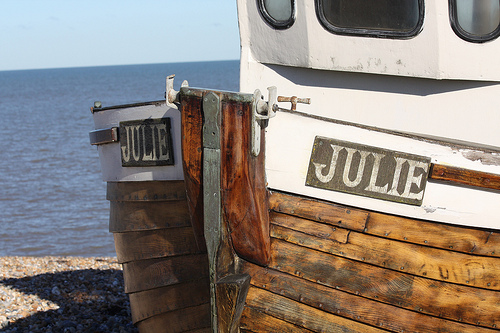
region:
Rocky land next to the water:
[1, 253, 130, 331]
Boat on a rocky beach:
[89, 2, 499, 330]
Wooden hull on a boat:
[104, 175, 499, 331]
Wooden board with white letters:
[301, 134, 433, 209]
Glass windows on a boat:
[247, 0, 499, 43]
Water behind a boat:
[2, 59, 241, 254]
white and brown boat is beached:
[86, 4, 496, 331]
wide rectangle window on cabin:
[310, 0, 427, 42]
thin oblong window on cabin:
[445, 0, 499, 45]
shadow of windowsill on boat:
[257, 54, 498, 98]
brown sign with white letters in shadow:
[115, 111, 177, 172]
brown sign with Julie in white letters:
[302, 127, 434, 208]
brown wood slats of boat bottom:
[227, 180, 497, 331]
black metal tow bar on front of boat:
[165, 65, 277, 330]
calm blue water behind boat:
[0, 60, 240, 252]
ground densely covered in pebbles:
[3, 254, 138, 331]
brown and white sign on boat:
[298, 135, 445, 212]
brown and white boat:
[87, 2, 498, 332]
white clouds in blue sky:
[7, 3, 62, 43]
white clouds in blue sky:
[64, 21, 121, 53]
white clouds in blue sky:
[140, 15, 200, 46]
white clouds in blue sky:
[30, 16, 104, 60]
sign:
[107, 98, 182, 175]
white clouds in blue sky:
[82, 13, 169, 44]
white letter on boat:
[311, 140, 345, 185]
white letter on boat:
[341, 146, 367, 186]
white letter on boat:
[365, 150, 389, 196]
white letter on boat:
[387, 153, 404, 199]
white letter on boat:
[402, 155, 426, 200]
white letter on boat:
[153, 123, 170, 163]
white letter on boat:
[148, 123, 158, 162]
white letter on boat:
[140, 123, 155, 163]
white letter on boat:
[128, 124, 143, 161]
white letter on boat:
[119, 124, 133, 164]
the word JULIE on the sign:
[304, 135, 430, 209]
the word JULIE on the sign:
[119, 117, 174, 167]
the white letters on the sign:
[303, 134, 429, 207]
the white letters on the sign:
[116, 115, 176, 167]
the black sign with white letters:
[303, 133, 430, 208]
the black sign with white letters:
[118, 117, 174, 167]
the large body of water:
[0, 59, 239, 256]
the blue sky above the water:
[1, 0, 242, 70]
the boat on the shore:
[1, 0, 499, 330]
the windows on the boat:
[88, 0, 499, 332]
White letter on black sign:
[111, 120, 131, 169]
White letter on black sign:
[125, 120, 142, 167]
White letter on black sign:
[140, 123, 150, 166]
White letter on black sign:
[146, 118, 161, 169]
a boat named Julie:
[289, 121, 444, 224]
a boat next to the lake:
[76, 42, 483, 293]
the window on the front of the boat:
[311, 3, 441, 43]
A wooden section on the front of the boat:
[254, 190, 493, 317]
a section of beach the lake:
[14, 231, 107, 293]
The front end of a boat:
[214, 7, 489, 315]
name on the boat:
[93, 88, 199, 183]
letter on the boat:
[292, 131, 351, 199]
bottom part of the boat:
[119, 187, 410, 330]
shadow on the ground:
[1, 237, 96, 324]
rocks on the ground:
[2, 247, 85, 322]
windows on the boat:
[256, 5, 454, 60]